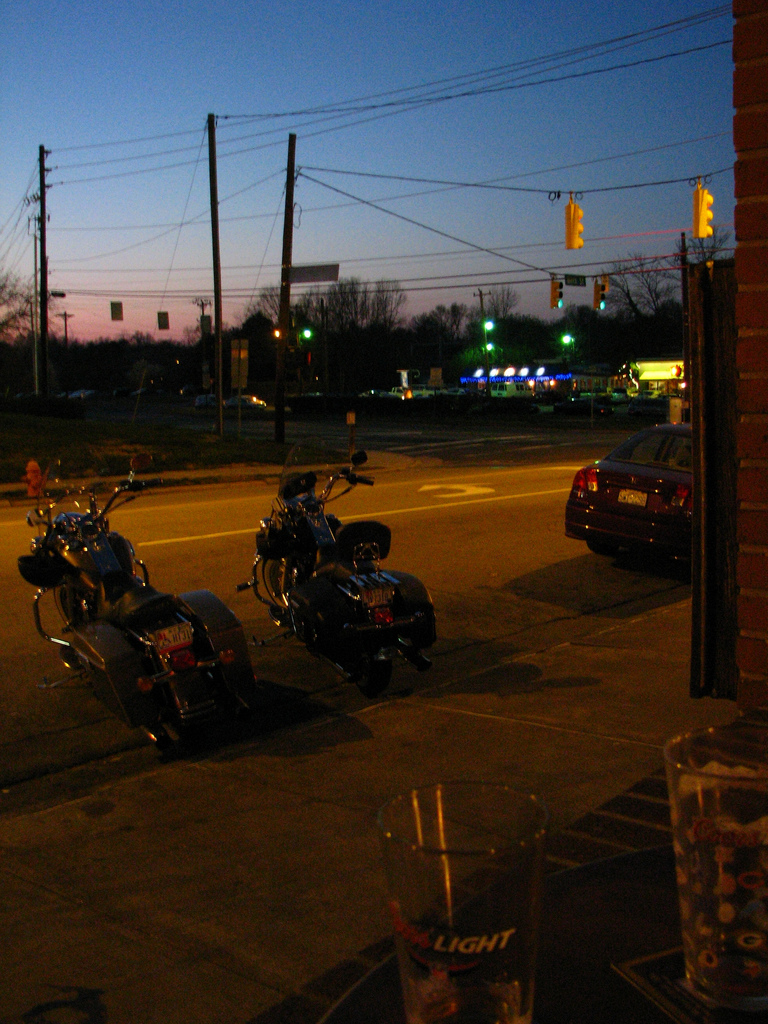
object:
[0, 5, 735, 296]
wires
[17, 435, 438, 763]
motorcycles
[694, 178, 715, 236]
traffic light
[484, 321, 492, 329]
light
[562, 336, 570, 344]
light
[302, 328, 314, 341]
light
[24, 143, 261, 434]
poles